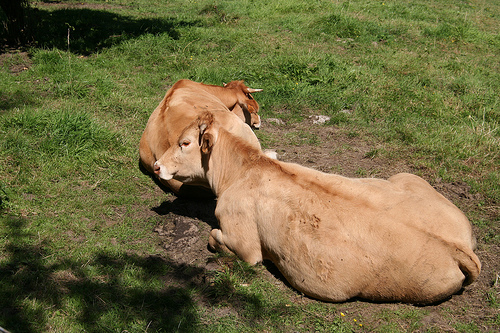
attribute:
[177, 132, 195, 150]
eyes — brown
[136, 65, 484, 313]
cow — Left eye